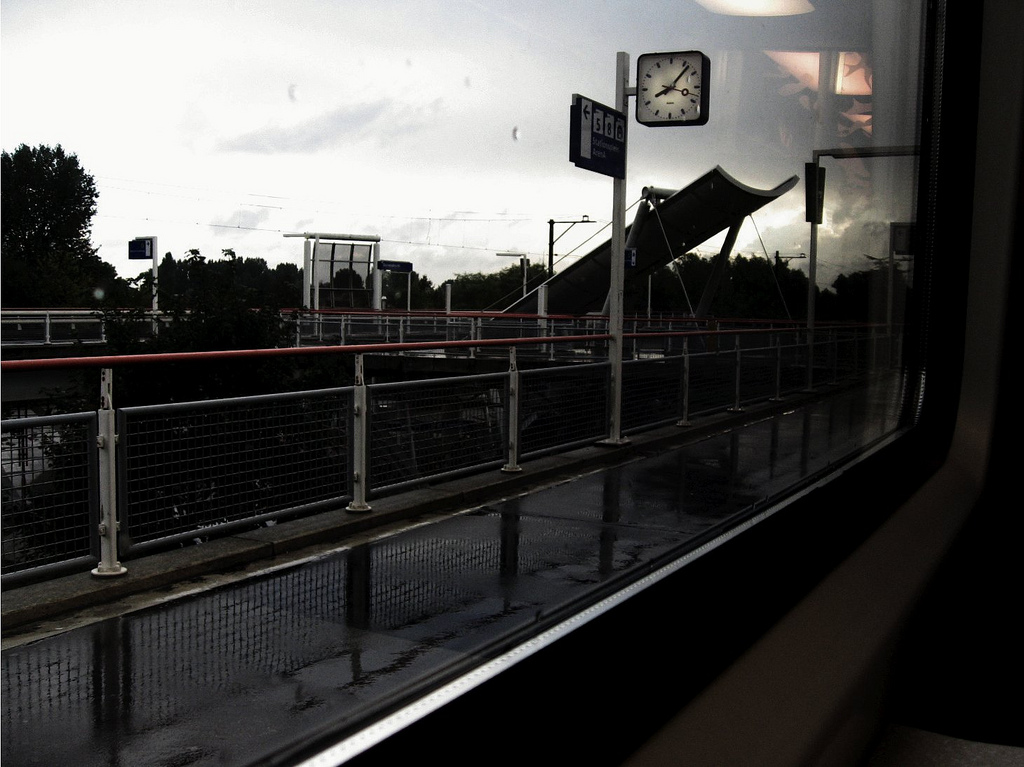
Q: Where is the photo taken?
A: Inside a train.